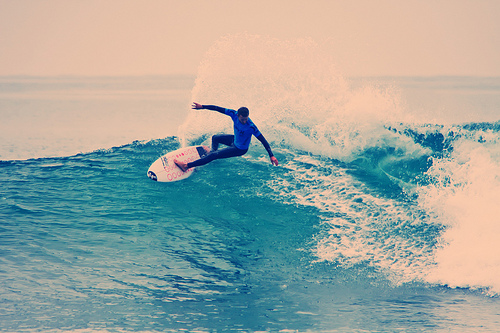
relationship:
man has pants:
[172, 101, 279, 172] [181, 131, 248, 168]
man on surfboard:
[172, 101, 279, 172] [145, 145, 212, 182]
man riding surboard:
[172, 101, 279, 172] [142, 137, 212, 184]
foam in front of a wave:
[332, 165, 428, 281] [1, 130, 498, 261]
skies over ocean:
[1, 1, 498, 76] [0, 74, 499, 331]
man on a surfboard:
[172, 101, 279, 172] [150, 142, 210, 181]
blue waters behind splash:
[0, 0, 499, 332] [176, 47, 496, 293]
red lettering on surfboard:
[163, 161, 181, 181] [143, 144, 208, 181]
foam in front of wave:
[332, 165, 428, 281] [17, 139, 131, 184]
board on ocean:
[146, 143, 213, 182] [34, 99, 394, 269]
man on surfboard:
[172, 101, 279, 172] [138, 142, 210, 182]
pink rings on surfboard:
[167, 148, 203, 176] [144, 139, 215, 183]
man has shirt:
[172, 101, 279, 172] [193, 98, 274, 158]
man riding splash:
[172, 101, 279, 172] [176, 47, 496, 293]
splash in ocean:
[176, 47, 496, 293] [0, 74, 499, 331]